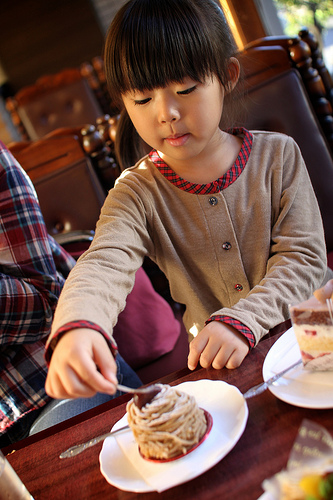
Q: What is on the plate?
A: Dessert.